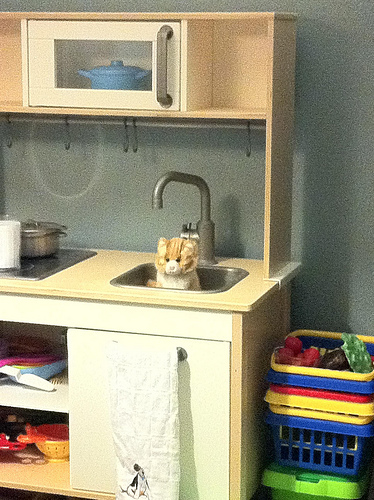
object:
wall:
[298, 0, 374, 326]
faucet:
[145, 169, 220, 228]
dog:
[115, 459, 154, 500]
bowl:
[73, 53, 157, 96]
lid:
[11, 215, 66, 241]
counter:
[0, 240, 304, 499]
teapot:
[75, 55, 144, 93]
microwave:
[14, 9, 188, 120]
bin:
[257, 464, 365, 500]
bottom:
[0, 452, 373, 500]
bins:
[257, 326, 373, 500]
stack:
[256, 327, 370, 498]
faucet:
[147, 161, 224, 270]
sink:
[108, 258, 249, 296]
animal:
[142, 228, 206, 296]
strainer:
[20, 421, 73, 465]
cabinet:
[0, 407, 70, 477]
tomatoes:
[273, 333, 320, 372]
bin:
[263, 324, 373, 379]